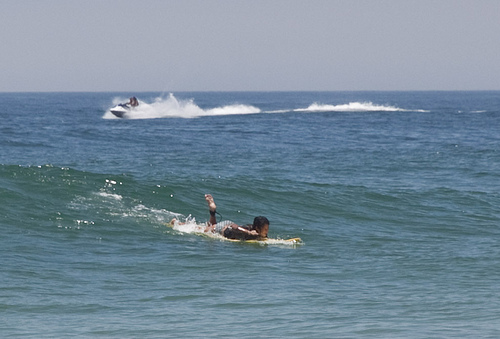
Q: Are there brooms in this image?
A: No, there are no brooms.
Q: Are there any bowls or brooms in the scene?
A: No, there are no brooms or bowls.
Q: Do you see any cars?
A: No, there are no cars.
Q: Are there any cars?
A: No, there are no cars.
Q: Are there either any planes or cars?
A: No, there are no cars or planes.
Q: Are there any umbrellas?
A: No, there are no umbrellas.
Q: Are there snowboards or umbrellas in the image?
A: No, there are no umbrellas or snowboards.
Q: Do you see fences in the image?
A: No, there are no fences.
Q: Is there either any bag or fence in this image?
A: No, there are no fences or bags.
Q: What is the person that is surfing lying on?
A: The person is lying on the surfboard.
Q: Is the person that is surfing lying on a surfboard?
A: Yes, the person is lying on a surfboard.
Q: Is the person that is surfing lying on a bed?
A: No, the person is lying on a surfboard.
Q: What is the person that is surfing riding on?
A: The person is riding on the surfboard.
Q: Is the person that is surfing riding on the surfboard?
A: Yes, the person is riding on the surfboard.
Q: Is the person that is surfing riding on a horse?
A: No, the person is riding on the surfboard.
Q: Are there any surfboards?
A: Yes, there is a surfboard.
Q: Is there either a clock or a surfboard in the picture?
A: Yes, there is a surfboard.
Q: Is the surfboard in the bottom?
A: Yes, the surfboard is in the bottom of the image.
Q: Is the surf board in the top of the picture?
A: No, the surf board is in the bottom of the image.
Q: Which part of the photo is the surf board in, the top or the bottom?
A: The surf board is in the bottom of the image.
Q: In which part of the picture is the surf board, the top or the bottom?
A: The surf board is in the bottom of the image.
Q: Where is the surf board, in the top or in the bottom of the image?
A: The surf board is in the bottom of the image.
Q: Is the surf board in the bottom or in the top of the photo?
A: The surf board is in the bottom of the image.